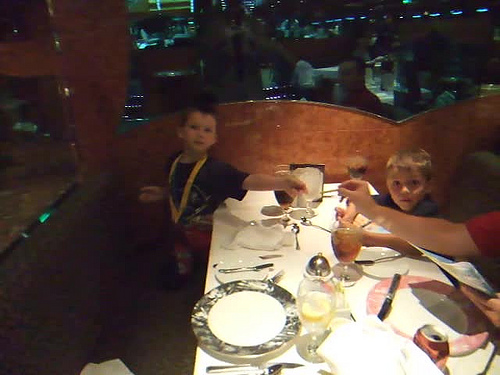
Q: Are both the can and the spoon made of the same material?
A: Yes, both the can and the spoon are made of metal.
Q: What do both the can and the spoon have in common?
A: The material, both the can and the spoon are metallic.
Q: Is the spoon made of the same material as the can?
A: Yes, both the spoon and the can are made of metal.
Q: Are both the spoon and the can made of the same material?
A: Yes, both the spoon and the can are made of metal.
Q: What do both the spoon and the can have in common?
A: The material, both the spoon and the can are metallic.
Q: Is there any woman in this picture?
A: No, there are no women.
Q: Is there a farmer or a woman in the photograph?
A: No, there are no women or farmers.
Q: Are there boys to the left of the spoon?
A: Yes, there is a boy to the left of the spoon.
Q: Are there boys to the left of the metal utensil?
A: Yes, there is a boy to the left of the spoon.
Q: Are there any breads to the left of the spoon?
A: No, there is a boy to the left of the spoon.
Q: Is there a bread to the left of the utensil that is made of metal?
A: No, there is a boy to the left of the spoon.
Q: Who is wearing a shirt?
A: The boy is wearing a shirt.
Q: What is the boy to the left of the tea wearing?
A: The boy is wearing a shirt.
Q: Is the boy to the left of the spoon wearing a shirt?
A: Yes, the boy is wearing a shirt.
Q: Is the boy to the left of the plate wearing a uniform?
A: No, the boy is wearing a shirt.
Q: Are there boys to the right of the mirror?
A: Yes, there is a boy to the right of the mirror.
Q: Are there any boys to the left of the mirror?
A: No, the boy is to the right of the mirror.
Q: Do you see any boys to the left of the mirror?
A: No, the boy is to the right of the mirror.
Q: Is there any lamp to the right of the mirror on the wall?
A: No, there is a boy to the right of the mirror.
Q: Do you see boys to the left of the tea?
A: Yes, there is a boy to the left of the tea.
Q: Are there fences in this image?
A: No, there are no fences.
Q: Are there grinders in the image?
A: No, there are no grinders.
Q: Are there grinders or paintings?
A: No, there are no grinders or paintings.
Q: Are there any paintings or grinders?
A: No, there are no grinders or paintings.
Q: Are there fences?
A: No, there are no fences.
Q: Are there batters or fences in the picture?
A: No, there are no fences or batters.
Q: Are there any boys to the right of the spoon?
A: Yes, there is a boy to the right of the spoon.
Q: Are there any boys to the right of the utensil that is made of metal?
A: Yes, there is a boy to the right of the spoon.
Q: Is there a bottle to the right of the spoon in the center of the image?
A: No, there is a boy to the right of the spoon.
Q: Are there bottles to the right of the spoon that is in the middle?
A: No, there is a boy to the right of the spoon.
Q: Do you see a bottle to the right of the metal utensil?
A: No, there is a boy to the right of the spoon.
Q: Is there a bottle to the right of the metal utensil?
A: No, there is a boy to the right of the spoon.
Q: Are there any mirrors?
A: Yes, there is a mirror.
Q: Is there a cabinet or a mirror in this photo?
A: Yes, there is a mirror.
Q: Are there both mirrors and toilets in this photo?
A: No, there is a mirror but no toilets.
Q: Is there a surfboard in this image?
A: No, there are no surfboards.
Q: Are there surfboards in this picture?
A: No, there are no surfboards.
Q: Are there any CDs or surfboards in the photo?
A: No, there are no surfboards or cds.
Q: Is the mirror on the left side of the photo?
A: Yes, the mirror is on the left of the image.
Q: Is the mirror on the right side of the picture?
A: No, the mirror is on the left of the image.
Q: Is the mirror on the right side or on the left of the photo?
A: The mirror is on the left of the image.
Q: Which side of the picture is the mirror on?
A: The mirror is on the left of the image.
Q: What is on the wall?
A: The mirror is on the wall.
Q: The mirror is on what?
A: The mirror is on the wall.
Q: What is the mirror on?
A: The mirror is on the wall.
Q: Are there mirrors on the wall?
A: Yes, there is a mirror on the wall.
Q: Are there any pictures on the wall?
A: No, there is a mirror on the wall.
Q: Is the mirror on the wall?
A: Yes, the mirror is on the wall.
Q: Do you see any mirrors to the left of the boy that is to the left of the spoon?
A: Yes, there is a mirror to the left of the boy.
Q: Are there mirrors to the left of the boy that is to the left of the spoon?
A: Yes, there is a mirror to the left of the boy.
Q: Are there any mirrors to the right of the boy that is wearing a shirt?
A: No, the mirror is to the left of the boy.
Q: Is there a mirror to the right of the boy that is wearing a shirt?
A: No, the mirror is to the left of the boy.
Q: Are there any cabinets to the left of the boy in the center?
A: No, there is a mirror to the left of the boy.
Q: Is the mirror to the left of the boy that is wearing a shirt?
A: Yes, the mirror is to the left of the boy.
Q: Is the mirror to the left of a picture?
A: No, the mirror is to the left of the boy.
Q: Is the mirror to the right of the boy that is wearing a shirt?
A: No, the mirror is to the left of the boy.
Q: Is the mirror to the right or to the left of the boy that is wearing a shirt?
A: The mirror is to the left of the boy.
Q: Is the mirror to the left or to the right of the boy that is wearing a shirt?
A: The mirror is to the left of the boy.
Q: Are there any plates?
A: Yes, there is a plate.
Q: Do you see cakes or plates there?
A: Yes, there is a plate.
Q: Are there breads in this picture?
A: No, there are no breads.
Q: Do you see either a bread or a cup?
A: No, there are no breads or cups.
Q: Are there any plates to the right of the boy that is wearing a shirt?
A: Yes, there is a plate to the right of the boy.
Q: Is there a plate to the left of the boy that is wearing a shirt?
A: No, the plate is to the right of the boy.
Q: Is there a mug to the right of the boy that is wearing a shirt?
A: No, there is a plate to the right of the boy.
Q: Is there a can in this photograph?
A: Yes, there is a can.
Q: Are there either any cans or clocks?
A: Yes, there is a can.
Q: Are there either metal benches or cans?
A: Yes, there is a metal can.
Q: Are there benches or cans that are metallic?
A: Yes, the can is metallic.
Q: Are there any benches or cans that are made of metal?
A: Yes, the can is made of metal.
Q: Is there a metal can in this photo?
A: Yes, there is a metal can.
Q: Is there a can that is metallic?
A: Yes, there is a can that is metallic.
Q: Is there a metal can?
A: Yes, there is a can that is made of metal.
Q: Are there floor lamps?
A: No, there are no floor lamps.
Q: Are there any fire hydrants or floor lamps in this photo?
A: No, there are no floor lamps or fire hydrants.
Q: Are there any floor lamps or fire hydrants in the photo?
A: No, there are no floor lamps or fire hydrants.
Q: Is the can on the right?
A: Yes, the can is on the right of the image.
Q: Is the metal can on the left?
A: No, the can is on the right of the image.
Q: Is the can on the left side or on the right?
A: The can is on the right of the image.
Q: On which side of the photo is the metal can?
A: The can is on the right of the image.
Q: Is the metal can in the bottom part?
A: Yes, the can is in the bottom of the image.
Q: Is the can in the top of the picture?
A: No, the can is in the bottom of the image.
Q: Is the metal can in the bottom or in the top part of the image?
A: The can is in the bottom of the image.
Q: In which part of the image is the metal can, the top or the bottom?
A: The can is in the bottom of the image.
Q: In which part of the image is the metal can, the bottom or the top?
A: The can is in the bottom of the image.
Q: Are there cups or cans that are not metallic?
A: No, there is a can but it is metallic.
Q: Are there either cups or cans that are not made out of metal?
A: No, there is a can but it is made of metal.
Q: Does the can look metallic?
A: Yes, the can is metallic.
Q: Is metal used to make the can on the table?
A: Yes, the can is made of metal.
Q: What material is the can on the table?
A: The can is made of metal.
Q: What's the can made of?
A: The can is made of metal.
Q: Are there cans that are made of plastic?
A: No, there is a can but it is made of metal.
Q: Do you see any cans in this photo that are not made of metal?
A: No, there is a can but it is made of metal.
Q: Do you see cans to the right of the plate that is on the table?
A: Yes, there is a can to the right of the plate.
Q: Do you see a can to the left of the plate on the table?
A: No, the can is to the right of the plate.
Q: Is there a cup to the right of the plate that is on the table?
A: No, there is a can to the right of the plate.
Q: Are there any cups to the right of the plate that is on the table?
A: No, there is a can to the right of the plate.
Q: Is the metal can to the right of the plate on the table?
A: Yes, the can is to the right of the plate.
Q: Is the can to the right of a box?
A: No, the can is to the right of the plate.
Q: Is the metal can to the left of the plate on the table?
A: No, the can is to the right of the plate.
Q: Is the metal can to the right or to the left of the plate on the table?
A: The can is to the right of the plate.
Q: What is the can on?
A: The can is on the table.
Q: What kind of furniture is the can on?
A: The can is on the table.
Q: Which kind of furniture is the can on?
A: The can is on the table.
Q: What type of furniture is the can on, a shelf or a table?
A: The can is on a table.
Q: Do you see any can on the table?
A: Yes, there is a can on the table.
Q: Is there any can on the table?
A: Yes, there is a can on the table.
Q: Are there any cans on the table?
A: Yes, there is a can on the table.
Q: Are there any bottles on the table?
A: No, there is a can on the table.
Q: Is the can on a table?
A: Yes, the can is on a table.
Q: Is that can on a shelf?
A: No, the can is on a table.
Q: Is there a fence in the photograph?
A: No, there are no fences.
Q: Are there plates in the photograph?
A: Yes, there is a plate.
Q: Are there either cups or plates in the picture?
A: Yes, there is a plate.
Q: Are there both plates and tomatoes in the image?
A: No, there is a plate but no tomatoes.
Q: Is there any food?
A: No, there is no food.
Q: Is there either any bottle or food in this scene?
A: No, there are no food or bottles.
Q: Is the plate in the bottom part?
A: Yes, the plate is in the bottom of the image.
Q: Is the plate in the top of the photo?
A: No, the plate is in the bottom of the image.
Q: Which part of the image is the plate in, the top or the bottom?
A: The plate is in the bottom of the image.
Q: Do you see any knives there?
A: Yes, there is a knife.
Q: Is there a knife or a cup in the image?
A: Yes, there is a knife.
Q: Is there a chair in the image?
A: No, there are no chairs.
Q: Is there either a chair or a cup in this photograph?
A: No, there are no chairs or cups.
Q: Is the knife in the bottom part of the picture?
A: Yes, the knife is in the bottom of the image.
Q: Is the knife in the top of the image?
A: No, the knife is in the bottom of the image.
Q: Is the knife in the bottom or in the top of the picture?
A: The knife is in the bottom of the image.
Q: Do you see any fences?
A: No, there are no fences.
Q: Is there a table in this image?
A: Yes, there is a table.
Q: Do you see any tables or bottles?
A: Yes, there is a table.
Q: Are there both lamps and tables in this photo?
A: No, there is a table but no lamps.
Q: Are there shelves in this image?
A: No, there are no shelves.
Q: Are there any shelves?
A: No, there are no shelves.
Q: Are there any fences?
A: No, there are no fences.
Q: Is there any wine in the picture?
A: Yes, there is wine.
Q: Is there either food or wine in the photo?
A: Yes, there is wine.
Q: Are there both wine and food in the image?
A: No, there is wine but no food.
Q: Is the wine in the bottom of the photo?
A: Yes, the wine is in the bottom of the image.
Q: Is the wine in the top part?
A: No, the wine is in the bottom of the image.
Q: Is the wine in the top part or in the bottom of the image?
A: The wine is in the bottom of the image.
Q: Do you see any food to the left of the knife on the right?
A: No, there is wine to the left of the knife.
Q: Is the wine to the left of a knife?
A: Yes, the wine is to the left of a knife.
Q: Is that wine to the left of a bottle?
A: No, the wine is to the left of a knife.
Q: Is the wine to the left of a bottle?
A: No, the wine is to the left of the plate.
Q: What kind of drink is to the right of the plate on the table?
A: The drink is wine.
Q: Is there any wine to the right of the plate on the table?
A: Yes, there is wine to the right of the plate.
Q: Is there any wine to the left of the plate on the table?
A: No, the wine is to the right of the plate.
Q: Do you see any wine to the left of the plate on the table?
A: No, the wine is to the right of the plate.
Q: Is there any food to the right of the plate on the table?
A: No, there is wine to the right of the plate.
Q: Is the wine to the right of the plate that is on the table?
A: Yes, the wine is to the right of the plate.